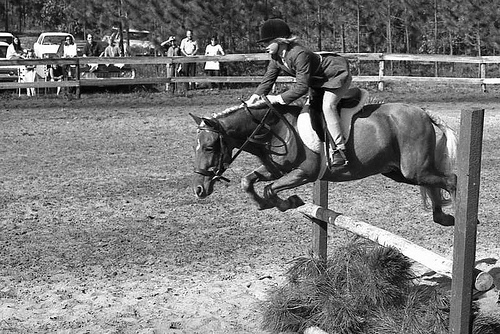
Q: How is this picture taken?
A: In black and white.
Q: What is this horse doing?
A: Jumping.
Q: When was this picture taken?
A: During daylight.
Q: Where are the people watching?
A: Behind the fence.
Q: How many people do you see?
A: 8.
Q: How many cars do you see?
A: 4.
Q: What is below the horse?
A: Wooden pole and brush.